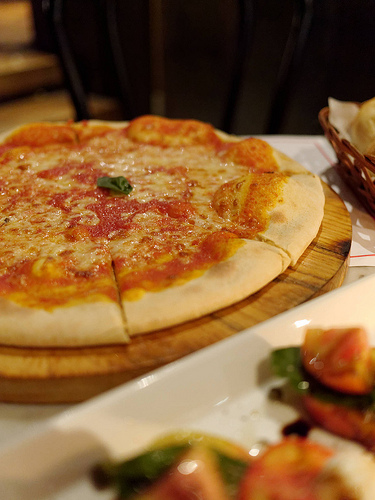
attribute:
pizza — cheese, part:
[7, 101, 350, 380]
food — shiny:
[256, 316, 373, 388]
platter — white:
[94, 269, 369, 387]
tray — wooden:
[0, 115, 353, 404]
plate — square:
[1, 266, 373, 499]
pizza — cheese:
[0, 98, 335, 350]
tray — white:
[2, 271, 372, 496]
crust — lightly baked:
[267, 168, 327, 261]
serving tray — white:
[0, 267, 375, 498]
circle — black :
[337, 238, 351, 261]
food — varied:
[16, 138, 372, 452]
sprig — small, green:
[91, 174, 135, 198]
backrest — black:
[93, 4, 315, 106]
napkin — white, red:
[349, 240, 373, 273]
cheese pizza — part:
[168, 131, 217, 149]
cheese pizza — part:
[46, 274, 103, 300]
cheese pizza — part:
[38, 155, 67, 181]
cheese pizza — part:
[70, 219, 134, 249]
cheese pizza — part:
[170, 188, 205, 213]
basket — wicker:
[314, 100, 374, 215]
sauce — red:
[89, 189, 153, 244]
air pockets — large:
[206, 132, 284, 232]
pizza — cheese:
[5, 99, 307, 346]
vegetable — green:
[97, 175, 132, 194]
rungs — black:
[75, 7, 317, 97]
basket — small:
[315, 94, 373, 218]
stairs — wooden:
[11, 15, 147, 129]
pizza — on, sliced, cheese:
[0, 114, 323, 347]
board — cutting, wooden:
[10, 100, 346, 444]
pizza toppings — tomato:
[0, 117, 304, 373]